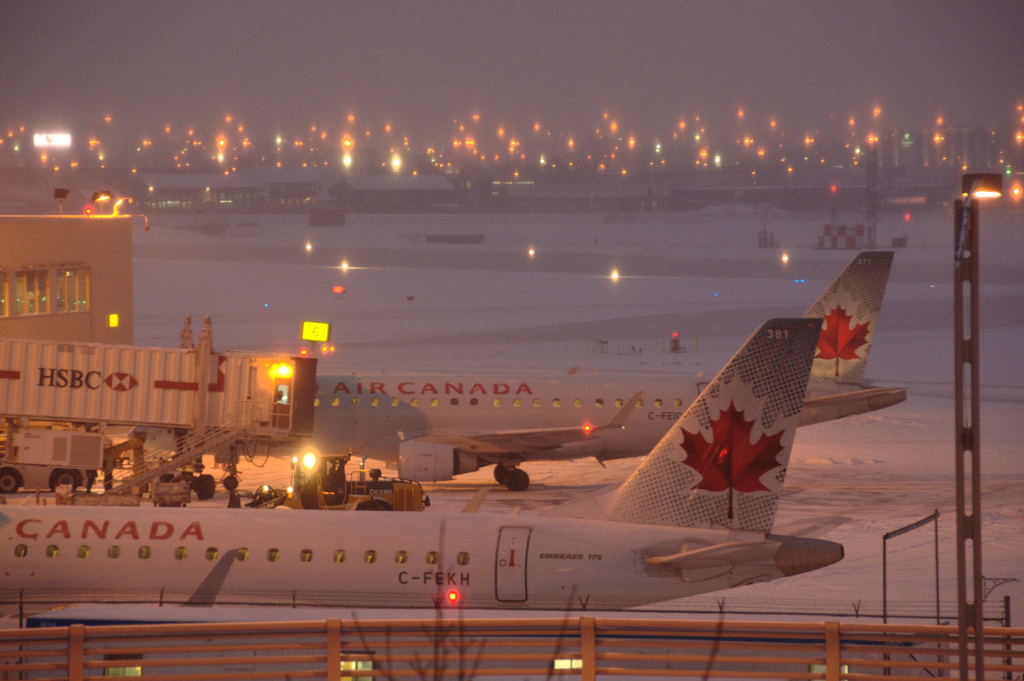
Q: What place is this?
A: It is a runway.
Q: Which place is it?
A: It is a runway.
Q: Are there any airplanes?
A: Yes, there is an airplane.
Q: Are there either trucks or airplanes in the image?
A: Yes, there is an airplane.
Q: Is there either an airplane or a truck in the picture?
A: Yes, there is an airplane.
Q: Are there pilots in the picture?
A: No, there are no pilots.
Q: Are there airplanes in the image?
A: Yes, there is an airplane.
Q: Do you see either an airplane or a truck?
A: Yes, there is an airplane.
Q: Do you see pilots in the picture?
A: No, there are no pilots.